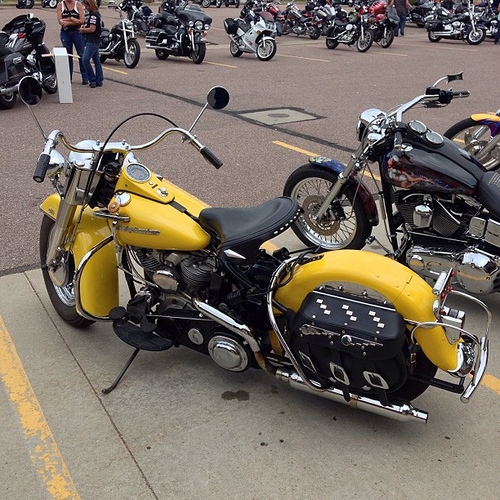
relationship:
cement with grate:
[225, 94, 331, 138] [266, 110, 290, 121]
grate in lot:
[266, 110, 290, 121] [13, 12, 484, 498]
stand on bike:
[101, 341, 141, 397] [9, 68, 481, 433]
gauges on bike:
[407, 119, 446, 149] [282, 72, 500, 298]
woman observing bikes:
[78, 1, 105, 89] [0, 9, 59, 110]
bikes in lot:
[0, 9, 59, 110] [13, 12, 484, 498]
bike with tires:
[223, 11, 278, 61] [226, 36, 276, 60]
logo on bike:
[113, 222, 159, 239] [9, 68, 481, 433]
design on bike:
[386, 166, 463, 202] [282, 72, 500, 298]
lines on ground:
[115, 62, 242, 78] [89, 29, 312, 113]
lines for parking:
[115, 62, 242, 78] [216, 10, 316, 93]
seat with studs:
[198, 196, 303, 252] [274, 204, 300, 234]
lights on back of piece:
[440, 267, 459, 307] [427, 260, 473, 345]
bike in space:
[18, 73, 490, 425] [23, 210, 477, 452]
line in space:
[4, 342, 78, 488] [5, 280, 362, 497]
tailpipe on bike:
[264, 366, 437, 426] [18, 73, 490, 425]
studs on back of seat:
[271, 203, 304, 236] [197, 193, 302, 261]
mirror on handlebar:
[188, 80, 232, 133] [128, 123, 226, 183]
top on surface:
[269, 110, 292, 120] [245, 96, 321, 137]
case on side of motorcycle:
[290, 277, 425, 405] [33, 135, 476, 436]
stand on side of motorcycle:
[101, 346, 141, 394] [25, 99, 484, 436]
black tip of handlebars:
[204, 144, 224, 174] [82, 102, 258, 199]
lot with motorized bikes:
[67, 222, 386, 468] [84, 62, 497, 310]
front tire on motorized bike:
[53, 205, 90, 284] [54, 178, 254, 379]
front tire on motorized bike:
[314, 184, 341, 254] [336, 175, 466, 202]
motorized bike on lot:
[245, 50, 273, 53] [252, 103, 264, 115]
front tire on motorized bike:
[246, 50, 282, 68] [242, 101, 262, 107]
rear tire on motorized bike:
[210, 101, 237, 118] [258, 51, 277, 79]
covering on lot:
[245, 98, 315, 125] [253, 100, 346, 180]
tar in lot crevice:
[245, 125, 282, 179] [237, 125, 305, 183]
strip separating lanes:
[22, 396, 65, 500] [22, 404, 154, 490]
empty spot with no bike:
[288, 54, 324, 80] [325, 104, 404, 172]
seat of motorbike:
[214, 173, 288, 297] [72, 163, 412, 260]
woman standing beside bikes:
[78, 1, 105, 89] [30, 53, 110, 86]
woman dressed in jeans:
[78, 1, 105, 89] [93, 103, 110, 132]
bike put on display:
[18, 73, 490, 425] [55, 212, 401, 472]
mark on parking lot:
[27, 405, 51, 500] [12, 399, 180, 499]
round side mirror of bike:
[209, 95, 230, 113] [45, 155, 305, 295]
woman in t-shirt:
[77, 1, 107, 87] [86, 10, 100, 40]